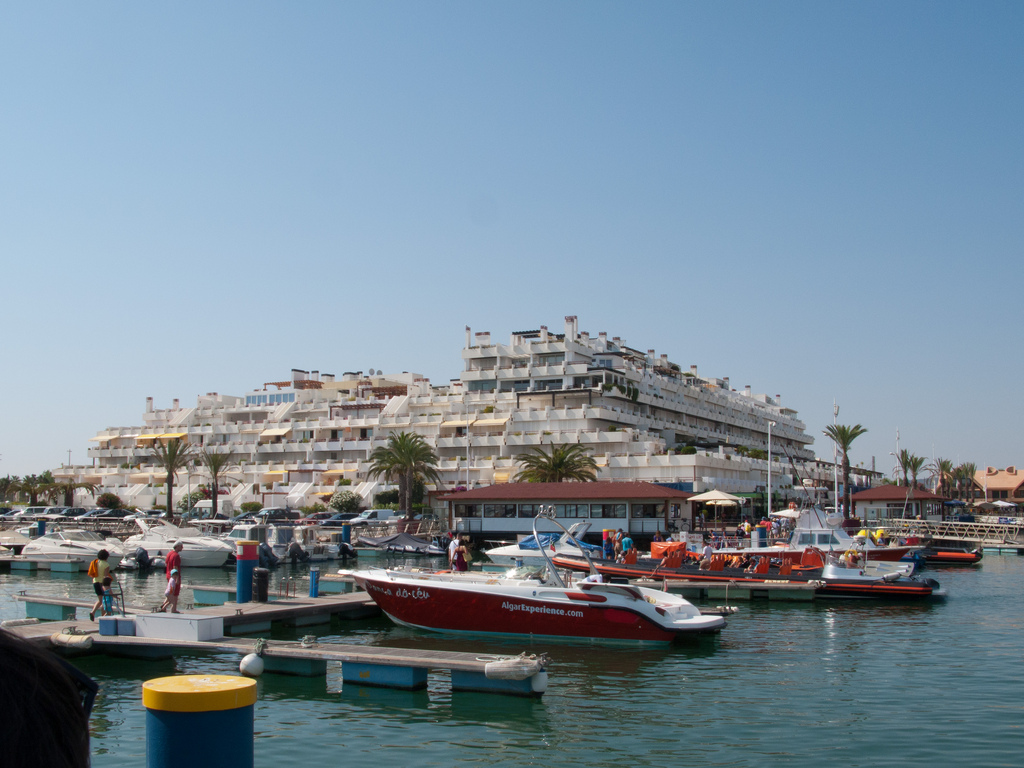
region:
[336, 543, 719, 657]
red and white boat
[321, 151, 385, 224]
white clouds in blue sky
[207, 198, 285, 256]
white clouds in blue sky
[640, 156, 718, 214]
white clouds in the blue sky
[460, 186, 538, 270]
white clouds in the blue sky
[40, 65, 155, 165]
white clouds in the blue sky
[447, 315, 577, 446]
The balcony is white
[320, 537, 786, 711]
The boat is red and white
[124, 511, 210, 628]
The person is wearing a red shirt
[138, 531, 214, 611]
The man is walking with a child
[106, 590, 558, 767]
The white buoy is on the dock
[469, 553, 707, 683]
The boat has white letters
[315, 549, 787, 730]
The boat is in the water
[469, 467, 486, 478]
window on the building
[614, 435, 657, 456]
window on the building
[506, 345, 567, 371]
window on the building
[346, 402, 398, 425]
window on the building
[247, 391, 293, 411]
window on the building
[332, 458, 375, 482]
window on the building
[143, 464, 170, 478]
window on the building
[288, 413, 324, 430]
window on the building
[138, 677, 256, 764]
The blue drum has a yellow top.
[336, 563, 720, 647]
The boat is red and white.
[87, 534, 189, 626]
Two adults each have a child on the dock.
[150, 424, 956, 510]
The palm trees are green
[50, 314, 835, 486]
The building has multiple levels.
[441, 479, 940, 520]
The roofs on the white buildings are red.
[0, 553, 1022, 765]
The water around the docks is calm.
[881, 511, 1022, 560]
A bridge with sides is over the water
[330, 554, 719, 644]
white boat in the calm water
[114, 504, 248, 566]
white boat in the calm water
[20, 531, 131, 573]
white boat in the calm water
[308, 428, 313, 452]
glass window on the building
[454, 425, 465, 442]
glass window on the building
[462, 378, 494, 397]
glass window on the building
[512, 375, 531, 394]
glass window on the building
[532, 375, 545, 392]
glass window on the building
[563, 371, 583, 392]
glass window on the building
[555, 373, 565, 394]
glass window on the building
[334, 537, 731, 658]
red and white boat on the dock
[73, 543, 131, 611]
woman walking on the pier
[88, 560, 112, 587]
woman wearing a green shirt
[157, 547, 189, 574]
man wearing a red shirt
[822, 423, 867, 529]
palm tree on the pier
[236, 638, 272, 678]
buoy on the side of the dock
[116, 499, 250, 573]
white boat on the pier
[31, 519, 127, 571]
white boat on the pier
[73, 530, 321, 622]
people walking on a dock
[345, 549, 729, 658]
red and white boat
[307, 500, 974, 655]
boats parked in a marina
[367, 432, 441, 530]
a green palm tree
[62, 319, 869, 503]
a large white commercial building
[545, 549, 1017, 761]
calm waters of a marina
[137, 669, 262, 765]
a blue and yellow post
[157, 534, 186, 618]
person with a child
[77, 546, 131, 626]
woman carrying a red purse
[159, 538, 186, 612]
person in a red shirt